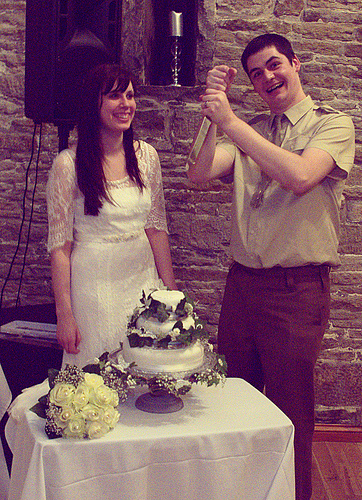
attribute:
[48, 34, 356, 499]
people — standing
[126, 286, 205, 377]
cake — white, cut, tiered, decorated, displayed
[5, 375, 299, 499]
table cloth — white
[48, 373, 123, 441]
rose — white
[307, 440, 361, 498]
floor — brown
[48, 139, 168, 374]
dress — white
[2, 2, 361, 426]
wall — brick, stone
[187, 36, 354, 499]
man — holding, smiling, playful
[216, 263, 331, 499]
pants — brown, black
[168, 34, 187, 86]
candle — silver, small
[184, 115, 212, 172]
knife — silver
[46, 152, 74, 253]
sleeve — lace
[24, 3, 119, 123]
speaker — black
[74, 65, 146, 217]
hair — long, dark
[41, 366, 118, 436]
bouquet — white, resting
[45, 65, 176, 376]
bride — laughing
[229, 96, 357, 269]
shirt — tan